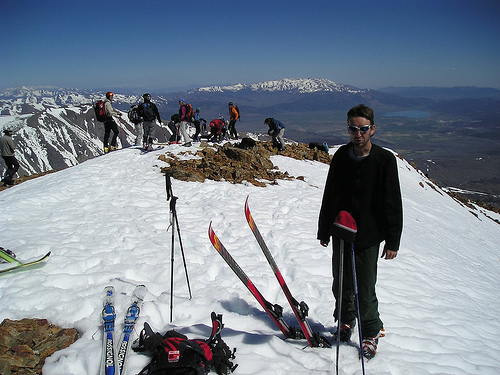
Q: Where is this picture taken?
A: On top of mountain.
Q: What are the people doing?
A: Skiing.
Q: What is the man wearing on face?
A: Sunglasses.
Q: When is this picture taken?
A: Daytime.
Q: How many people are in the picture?
A: Eleven.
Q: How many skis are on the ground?
A: Five.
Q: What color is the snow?
A: White.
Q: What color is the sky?
A: Blue.